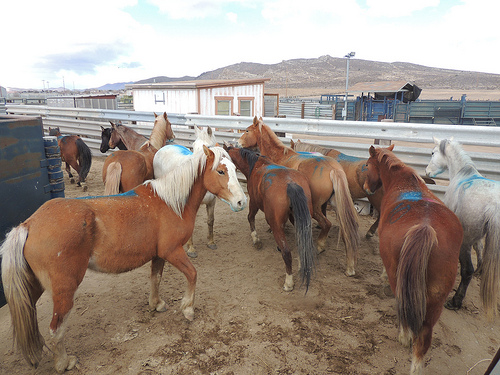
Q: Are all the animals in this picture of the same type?
A: Yes, all the animals are horses.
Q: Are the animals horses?
A: Yes, all the animals are horses.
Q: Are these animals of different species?
A: No, all the animals are horses.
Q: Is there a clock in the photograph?
A: No, there are no clocks.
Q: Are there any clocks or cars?
A: No, there are no clocks or cars.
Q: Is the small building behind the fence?
A: Yes, the building is behind the fence.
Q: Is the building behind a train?
A: No, the building is behind the fence.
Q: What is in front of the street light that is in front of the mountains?
A: The building is in front of the lamp post.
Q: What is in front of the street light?
A: The building is in front of the lamp post.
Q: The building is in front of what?
A: The building is in front of the streetlight.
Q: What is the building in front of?
A: The building is in front of the streetlight.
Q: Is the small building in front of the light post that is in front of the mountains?
A: Yes, the building is in front of the lamp post.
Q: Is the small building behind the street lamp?
A: No, the building is in front of the street lamp.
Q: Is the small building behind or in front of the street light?
A: The building is in front of the street light.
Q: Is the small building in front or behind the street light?
A: The building is in front of the street light.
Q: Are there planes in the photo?
A: No, there are no planes.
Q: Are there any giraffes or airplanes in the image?
A: No, there are no airplanes or giraffes.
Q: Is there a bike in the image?
A: No, there are no bikes.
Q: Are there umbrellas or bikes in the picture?
A: No, there are no bikes or umbrellas.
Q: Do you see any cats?
A: No, there are no cats.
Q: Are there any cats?
A: No, there are no cats.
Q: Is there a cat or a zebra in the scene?
A: No, there are no cats or zebras.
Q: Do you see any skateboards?
A: No, there are no skateboards.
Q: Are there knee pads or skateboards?
A: No, there are no skateboards or knee pads.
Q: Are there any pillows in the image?
A: No, there are no pillows.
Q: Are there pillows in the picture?
A: No, there are no pillows.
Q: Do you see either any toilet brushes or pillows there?
A: No, there are no pillows or toilet brushes.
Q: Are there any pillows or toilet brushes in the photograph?
A: No, there are no pillows or toilet brushes.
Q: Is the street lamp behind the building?
A: Yes, the street lamp is behind the building.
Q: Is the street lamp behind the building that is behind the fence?
A: Yes, the street lamp is behind the building.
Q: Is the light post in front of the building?
A: No, the light post is behind the building.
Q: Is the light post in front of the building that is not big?
A: No, the light post is behind the building.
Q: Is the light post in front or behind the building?
A: The light post is behind the building.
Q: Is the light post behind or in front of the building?
A: The light post is behind the building.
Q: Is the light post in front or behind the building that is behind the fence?
A: The light post is behind the building.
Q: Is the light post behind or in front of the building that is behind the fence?
A: The light post is behind the building.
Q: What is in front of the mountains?
A: The street light is in front of the mountains.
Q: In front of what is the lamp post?
A: The lamp post is in front of the mountains.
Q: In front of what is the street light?
A: The lamp post is in front of the mountains.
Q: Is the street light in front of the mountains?
A: Yes, the street light is in front of the mountains.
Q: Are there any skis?
A: No, there are no skis.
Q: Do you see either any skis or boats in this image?
A: No, there are no skis or boats.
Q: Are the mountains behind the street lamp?
A: Yes, the mountains are behind the street lamp.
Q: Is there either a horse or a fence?
A: Yes, there are horses.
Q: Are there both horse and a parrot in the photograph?
A: No, there are horses but no parrots.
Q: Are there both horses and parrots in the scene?
A: No, there are horses but no parrots.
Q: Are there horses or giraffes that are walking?
A: Yes, the horses are walking.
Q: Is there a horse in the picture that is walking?
A: Yes, there are horses that are walking.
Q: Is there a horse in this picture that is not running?
A: Yes, there are horses that are walking.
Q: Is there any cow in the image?
A: No, there are no cows.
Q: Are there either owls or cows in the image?
A: No, there are no cows or owls.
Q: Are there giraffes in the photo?
A: No, there are no giraffes.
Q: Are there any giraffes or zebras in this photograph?
A: No, there are no giraffes or zebras.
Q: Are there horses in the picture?
A: Yes, there is a horse.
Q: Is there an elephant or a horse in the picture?
A: Yes, there is a horse.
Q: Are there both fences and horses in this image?
A: Yes, there are both a horse and a fence.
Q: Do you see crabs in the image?
A: No, there are no crabs.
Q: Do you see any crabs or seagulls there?
A: No, there are no crabs or seagulls.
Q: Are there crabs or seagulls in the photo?
A: No, there are no crabs or seagulls.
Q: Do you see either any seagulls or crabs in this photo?
A: No, there are no crabs or seagulls.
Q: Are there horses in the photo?
A: Yes, there is a horse.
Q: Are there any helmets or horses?
A: Yes, there is a horse.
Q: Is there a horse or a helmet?
A: Yes, there is a horse.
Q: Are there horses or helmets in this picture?
A: Yes, there is a horse.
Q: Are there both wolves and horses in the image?
A: No, there is a horse but no wolves.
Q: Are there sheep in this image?
A: No, there are no sheep.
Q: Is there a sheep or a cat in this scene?
A: No, there are no sheep or cats.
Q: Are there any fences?
A: Yes, there is a fence.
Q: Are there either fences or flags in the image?
A: Yes, there is a fence.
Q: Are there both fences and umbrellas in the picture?
A: No, there is a fence but no umbrellas.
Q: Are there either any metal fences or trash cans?
A: Yes, there is a metal fence.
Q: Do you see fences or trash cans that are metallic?
A: Yes, the fence is metallic.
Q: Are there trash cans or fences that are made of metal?
A: Yes, the fence is made of metal.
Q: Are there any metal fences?
A: Yes, there is a fence that is made of metal.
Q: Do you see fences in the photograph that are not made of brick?
A: Yes, there is a fence that is made of metal.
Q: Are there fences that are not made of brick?
A: Yes, there is a fence that is made of metal.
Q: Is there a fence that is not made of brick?
A: Yes, there is a fence that is made of metal.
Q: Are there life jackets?
A: No, there are no life jackets.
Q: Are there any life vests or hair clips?
A: No, there are no life vests or hair clips.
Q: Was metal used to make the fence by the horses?
A: Yes, the fence is made of metal.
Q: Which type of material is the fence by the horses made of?
A: The fence is made of metal.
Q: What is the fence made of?
A: The fence is made of metal.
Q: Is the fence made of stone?
A: No, the fence is made of metal.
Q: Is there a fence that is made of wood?
A: No, there is a fence but it is made of metal.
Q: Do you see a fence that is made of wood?
A: No, there is a fence but it is made of metal.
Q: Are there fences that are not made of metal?
A: No, there is a fence but it is made of metal.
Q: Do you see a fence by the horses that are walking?
A: Yes, there is a fence by the horses.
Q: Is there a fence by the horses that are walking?
A: Yes, there is a fence by the horses.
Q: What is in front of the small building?
A: The fence is in front of the building.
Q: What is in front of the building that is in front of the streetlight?
A: The fence is in front of the building.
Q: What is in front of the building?
A: The fence is in front of the building.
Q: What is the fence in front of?
A: The fence is in front of the building.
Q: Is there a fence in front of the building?
A: Yes, there is a fence in front of the building.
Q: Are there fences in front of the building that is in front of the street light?
A: Yes, there is a fence in front of the building.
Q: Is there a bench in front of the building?
A: No, there is a fence in front of the building.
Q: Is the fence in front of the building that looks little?
A: Yes, the fence is in front of the building.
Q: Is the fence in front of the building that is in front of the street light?
A: Yes, the fence is in front of the building.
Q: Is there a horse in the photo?
A: Yes, there is a horse.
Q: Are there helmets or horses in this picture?
A: Yes, there is a horse.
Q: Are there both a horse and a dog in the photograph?
A: No, there is a horse but no dogs.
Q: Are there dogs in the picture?
A: No, there are no dogs.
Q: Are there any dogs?
A: No, there are no dogs.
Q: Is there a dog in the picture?
A: No, there are no dogs.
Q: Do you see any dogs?
A: No, there are no dogs.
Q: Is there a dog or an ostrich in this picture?
A: No, there are no dogs or ostriches.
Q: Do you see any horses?
A: Yes, there is a horse.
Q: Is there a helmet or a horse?
A: Yes, there is a horse.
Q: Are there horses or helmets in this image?
A: Yes, there is a horse.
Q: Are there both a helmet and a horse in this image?
A: No, there is a horse but no helmets.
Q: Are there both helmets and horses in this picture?
A: No, there is a horse but no helmets.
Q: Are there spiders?
A: No, there are no spiders.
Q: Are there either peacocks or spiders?
A: No, there are no spiders or peacocks.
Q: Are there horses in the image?
A: Yes, there is a horse.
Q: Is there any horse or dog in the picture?
A: Yes, there is a horse.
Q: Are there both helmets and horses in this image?
A: No, there is a horse but no helmets.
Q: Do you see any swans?
A: No, there are no swans.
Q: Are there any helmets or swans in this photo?
A: No, there are no swans or helmets.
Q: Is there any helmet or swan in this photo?
A: No, there are no swans or helmets.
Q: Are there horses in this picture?
A: Yes, there is a horse.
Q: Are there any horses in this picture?
A: Yes, there is a horse.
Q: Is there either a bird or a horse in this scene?
A: Yes, there is a horse.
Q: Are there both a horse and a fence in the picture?
A: Yes, there are both a horse and a fence.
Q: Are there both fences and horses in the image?
A: Yes, there are both a horse and a fence.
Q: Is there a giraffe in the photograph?
A: No, there are no giraffes.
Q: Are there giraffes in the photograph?
A: No, there are no giraffes.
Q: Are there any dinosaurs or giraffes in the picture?
A: No, there are no giraffes or dinosaurs.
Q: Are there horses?
A: Yes, there is a horse.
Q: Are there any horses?
A: Yes, there is a horse.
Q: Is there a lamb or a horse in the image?
A: Yes, there is a horse.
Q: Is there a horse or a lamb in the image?
A: Yes, there is a horse.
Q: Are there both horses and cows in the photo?
A: No, there is a horse but no cows.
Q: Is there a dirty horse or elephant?
A: Yes, there is a dirty horse.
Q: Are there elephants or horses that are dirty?
A: Yes, the horse is dirty.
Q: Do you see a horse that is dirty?
A: Yes, there is a dirty horse.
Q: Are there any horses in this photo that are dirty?
A: Yes, there is a dirty horse.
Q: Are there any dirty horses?
A: Yes, there is a dirty horse.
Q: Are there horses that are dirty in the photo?
A: Yes, there is a dirty horse.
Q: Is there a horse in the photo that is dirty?
A: Yes, there is a horse that is dirty.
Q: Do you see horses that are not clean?
A: Yes, there is a dirty horse.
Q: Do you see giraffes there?
A: No, there are no giraffes.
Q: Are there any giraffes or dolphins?
A: No, there are no giraffes or dolphins.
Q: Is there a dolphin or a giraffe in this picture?
A: No, there are no giraffes or dolphins.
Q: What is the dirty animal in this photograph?
A: The animal is a horse.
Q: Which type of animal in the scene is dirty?
A: The animal is a horse.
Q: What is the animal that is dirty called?
A: The animal is a horse.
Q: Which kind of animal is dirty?
A: The animal is a horse.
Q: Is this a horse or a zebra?
A: This is a horse.